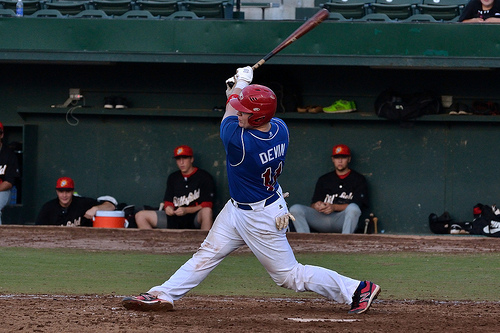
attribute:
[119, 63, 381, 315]
player — swinging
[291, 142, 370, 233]
man — sitting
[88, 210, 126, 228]
cooler — orange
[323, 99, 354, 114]
sneaker — green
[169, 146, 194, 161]
cap — red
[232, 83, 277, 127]
helmet — red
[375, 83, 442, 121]
bag — black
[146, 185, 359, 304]
pants — white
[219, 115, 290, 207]
jersey — blue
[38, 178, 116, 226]
guy — leaning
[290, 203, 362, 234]
pants — grey, gray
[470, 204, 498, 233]
clothes — red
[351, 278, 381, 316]
shoe — red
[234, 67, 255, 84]
glove — white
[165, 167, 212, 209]
shirt — black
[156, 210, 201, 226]
shorts — black